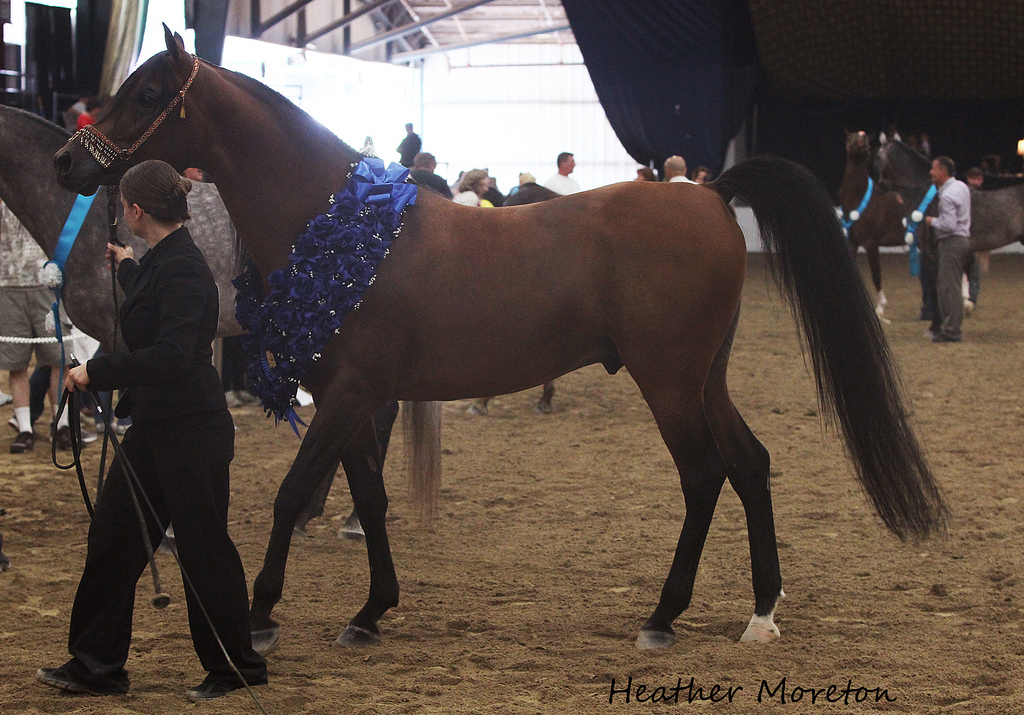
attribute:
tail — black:
[722, 156, 972, 550]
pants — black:
[72, 412, 253, 710]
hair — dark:
[107, 164, 194, 226]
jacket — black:
[94, 257, 231, 425]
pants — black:
[64, 390, 270, 673]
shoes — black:
[35, 640, 274, 698]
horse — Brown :
[2, 61, 247, 461]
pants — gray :
[72, 403, 266, 675]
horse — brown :
[876, 106, 938, 312]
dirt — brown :
[445, 491, 610, 711]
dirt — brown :
[435, 403, 622, 697]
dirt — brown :
[439, 399, 635, 706]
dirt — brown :
[411, 406, 624, 701]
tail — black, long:
[714, 144, 952, 547]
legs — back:
[631, 251, 800, 649]